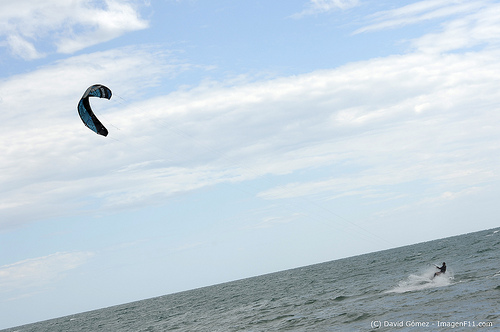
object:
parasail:
[76, 85, 111, 136]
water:
[0, 226, 499, 331]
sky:
[0, 0, 499, 332]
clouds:
[140, 46, 499, 194]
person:
[434, 262, 447, 278]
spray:
[396, 273, 454, 289]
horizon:
[0, 226, 500, 332]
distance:
[0, 0, 499, 327]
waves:
[254, 279, 366, 310]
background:
[0, 0, 500, 332]